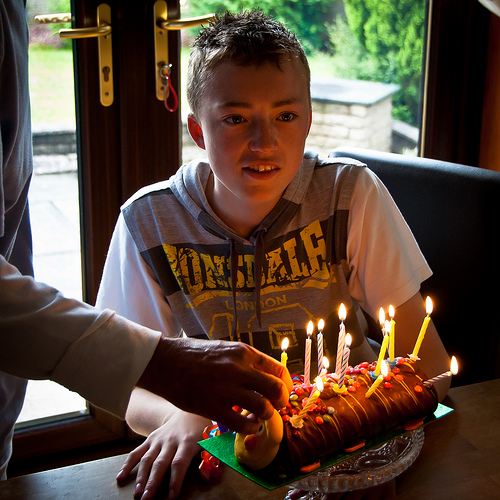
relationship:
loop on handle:
[162, 74, 178, 112] [153, 0, 215, 101]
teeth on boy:
[245, 162, 280, 173] [78, 6, 473, 496]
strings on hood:
[222, 235, 269, 327] [157, 153, 314, 248]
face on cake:
[231, 402, 283, 469] [226, 355, 435, 470]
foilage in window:
[360, 25, 380, 55] [177, 0, 420, 150]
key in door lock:
[160, 78, 176, 110] [155, 51, 167, 73]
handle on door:
[47, 26, 114, 46] [21, 4, 331, 421]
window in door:
[28, 2, 80, 295] [31, 0, 468, 294]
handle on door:
[58, 23, 110, 42] [86, 1, 196, 156]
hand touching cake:
[163, 332, 290, 432] [231, 351, 440, 481]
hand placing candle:
[157, 315, 297, 442] [280, 335, 292, 369]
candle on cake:
[280, 335, 292, 369] [230, 278, 467, 475]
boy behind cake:
[78, 6, 473, 496] [231, 351, 440, 481]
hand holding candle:
[155, 328, 302, 424] [243, 325, 304, 405]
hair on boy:
[183, 10, 314, 100] [110, 9, 460, 497]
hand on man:
[157, 302, 329, 402] [4, 5, 289, 497]